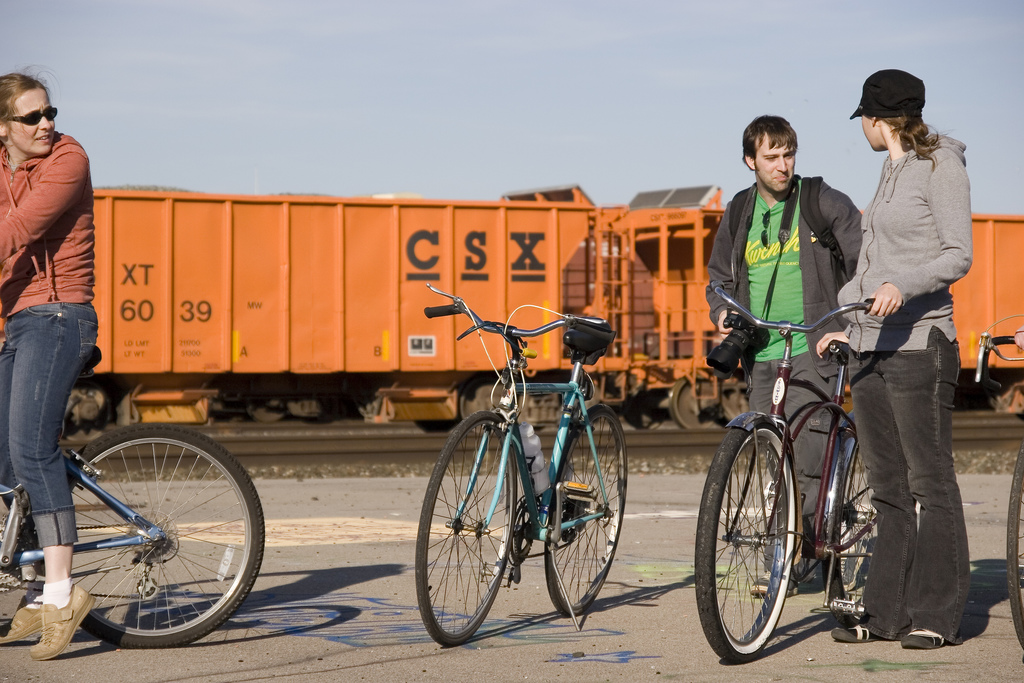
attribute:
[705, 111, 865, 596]
person — standing up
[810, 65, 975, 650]
person — standing up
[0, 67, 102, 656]
person — standing up